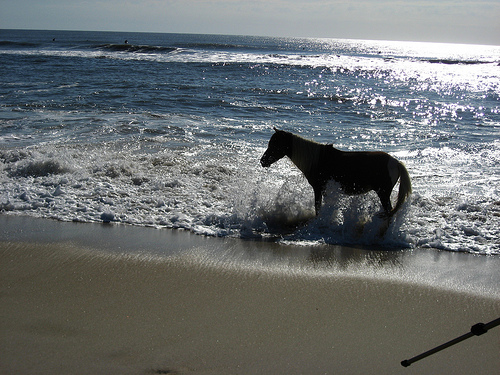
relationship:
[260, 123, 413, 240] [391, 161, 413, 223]
horse has tail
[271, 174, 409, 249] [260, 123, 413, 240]
wave near horse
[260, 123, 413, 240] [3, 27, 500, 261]
horse in ocean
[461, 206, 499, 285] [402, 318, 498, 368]
object has shadow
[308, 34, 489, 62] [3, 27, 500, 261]
reflection on ocean